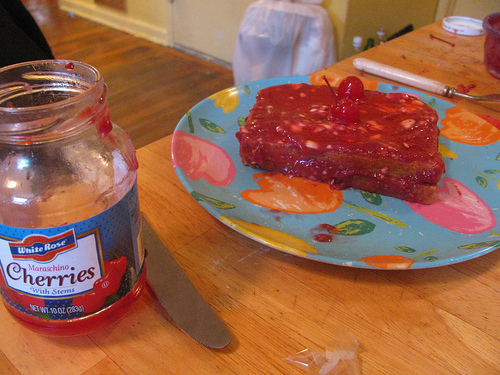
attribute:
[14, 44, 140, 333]
jar — empty, glass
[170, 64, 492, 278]
plate — floral, blue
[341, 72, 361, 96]
cherry — red, small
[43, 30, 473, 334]
table — wood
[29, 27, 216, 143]
floor — wooden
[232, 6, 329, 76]
plastic — clear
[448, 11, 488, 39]
cover — white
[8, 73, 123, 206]
glass — clear